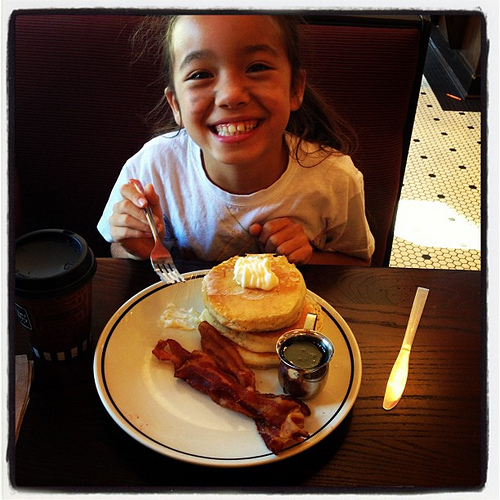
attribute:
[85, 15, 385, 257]
girl — smiling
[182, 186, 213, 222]
shirt — white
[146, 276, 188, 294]
plate — white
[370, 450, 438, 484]
table — wooden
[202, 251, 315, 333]
pancakes — brown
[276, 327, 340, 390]
cup — small, plastic, mettalic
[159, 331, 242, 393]
bacon — brown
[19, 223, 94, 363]
coffee cup — plastic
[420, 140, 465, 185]
floor — white, black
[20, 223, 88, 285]
lid — black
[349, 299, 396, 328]
lines — dark